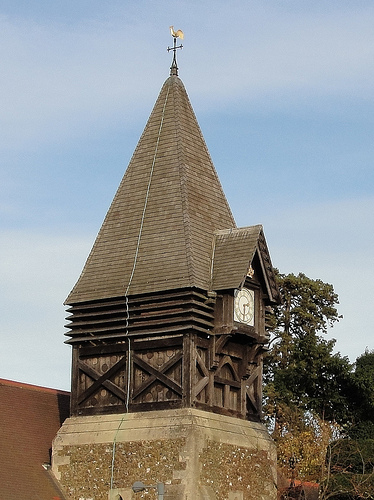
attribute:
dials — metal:
[244, 304, 252, 307]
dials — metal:
[241, 304, 245, 320]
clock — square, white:
[232, 285, 256, 328]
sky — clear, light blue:
[6, 9, 372, 368]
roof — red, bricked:
[160, 172, 238, 271]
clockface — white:
[235, 286, 255, 325]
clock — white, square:
[234, 287, 253, 322]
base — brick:
[52, 414, 282, 499]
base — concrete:
[62, 412, 307, 487]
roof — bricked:
[62, 76, 282, 303]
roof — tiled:
[63, 74, 280, 327]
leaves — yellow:
[258, 395, 361, 492]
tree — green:
[295, 292, 317, 319]